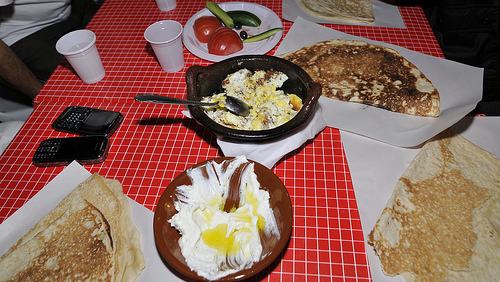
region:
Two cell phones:
[30, 106, 122, 165]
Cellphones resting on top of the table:
[28, 90, 132, 180]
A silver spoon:
[123, 89, 258, 119]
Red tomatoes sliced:
[190, 13, 243, 56]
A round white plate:
[179, 3, 286, 61]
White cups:
[48, 25, 185, 79]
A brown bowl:
[151, 158, 294, 279]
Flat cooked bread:
[4, 175, 145, 280]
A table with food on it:
[12, 0, 498, 271]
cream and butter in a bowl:
[170, 174, 279, 274]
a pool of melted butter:
[200, 222, 241, 254]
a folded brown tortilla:
[362, 129, 499, 276]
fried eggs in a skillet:
[198, 61, 300, 138]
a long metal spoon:
[128, 85, 244, 114]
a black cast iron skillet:
[180, 53, 321, 143]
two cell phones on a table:
[31, 101, 123, 166]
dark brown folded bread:
[281, 35, 442, 122]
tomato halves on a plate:
[187, 14, 244, 53]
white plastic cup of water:
[53, 28, 105, 86]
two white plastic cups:
[51, 18, 189, 83]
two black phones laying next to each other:
[29, 94, 125, 171]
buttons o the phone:
[58, 108, 81, 127]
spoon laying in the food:
[123, 87, 257, 115]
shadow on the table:
[135, 114, 214, 148]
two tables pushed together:
[1, 0, 491, 280]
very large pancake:
[6, 171, 149, 280]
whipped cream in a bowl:
[151, 153, 306, 279]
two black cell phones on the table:
[31, 105, 123, 165]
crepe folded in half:
[276, 38, 441, 118]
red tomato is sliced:
[207, 25, 243, 55]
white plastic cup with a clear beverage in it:
[53, 28, 106, 85]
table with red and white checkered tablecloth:
[3, 0, 448, 280]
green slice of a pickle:
[206, 1, 237, 28]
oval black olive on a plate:
[239, 29, 248, 39]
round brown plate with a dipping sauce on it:
[153, 153, 294, 278]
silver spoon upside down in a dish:
[133, 91, 249, 115]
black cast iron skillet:
[184, 53, 321, 143]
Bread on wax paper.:
[288, 26, 495, 168]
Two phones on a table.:
[28, 100, 135, 177]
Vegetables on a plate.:
[189, 2, 291, 54]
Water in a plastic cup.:
[58, 28, 106, 84]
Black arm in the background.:
[1, 38, 38, 115]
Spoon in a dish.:
[126, 76, 239, 120]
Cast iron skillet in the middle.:
[168, 46, 327, 147]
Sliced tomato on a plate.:
[209, 25, 241, 55]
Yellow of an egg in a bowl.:
[198, 225, 242, 247]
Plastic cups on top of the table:
[48, 26, 223, 64]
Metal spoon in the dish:
[145, 90, 270, 137]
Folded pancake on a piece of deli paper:
[295, 15, 440, 145]